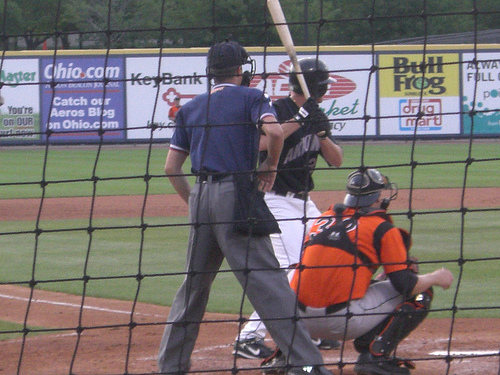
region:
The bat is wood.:
[268, 2, 316, 116]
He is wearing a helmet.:
[290, 51, 340, 93]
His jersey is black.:
[263, 95, 343, 187]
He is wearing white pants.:
[235, 189, 326, 372]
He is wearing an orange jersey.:
[284, 196, 404, 311]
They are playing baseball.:
[10, 25, 497, 373]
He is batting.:
[230, 9, 333, 370]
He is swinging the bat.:
[246, 7, 353, 359]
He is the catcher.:
[300, 168, 453, 362]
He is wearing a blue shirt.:
[153, 49, 282, 191]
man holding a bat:
[290, 30, 336, 172]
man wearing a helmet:
[270, 0, 350, 200]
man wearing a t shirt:
[280, 37, 346, 192]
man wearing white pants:
[266, 0, 326, 238]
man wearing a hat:
[145, 35, 317, 370]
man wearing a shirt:
[110, 25, 312, 367]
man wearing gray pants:
[106, 26, 303, 367]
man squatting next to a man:
[315, 150, 455, 367]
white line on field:
[15, 285, 140, 325]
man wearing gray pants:
[315, 156, 460, 368]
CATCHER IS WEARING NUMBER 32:
[287, 156, 439, 354]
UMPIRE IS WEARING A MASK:
[196, 40, 280, 95]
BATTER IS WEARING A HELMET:
[280, 51, 345, 123]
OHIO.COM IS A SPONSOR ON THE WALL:
[39, 55, 151, 163]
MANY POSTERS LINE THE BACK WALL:
[0, 40, 497, 155]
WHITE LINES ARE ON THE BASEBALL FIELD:
[4, 287, 184, 343]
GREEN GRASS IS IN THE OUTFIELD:
[5, 147, 498, 202]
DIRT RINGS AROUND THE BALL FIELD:
[10, 192, 497, 217]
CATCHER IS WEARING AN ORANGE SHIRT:
[298, 167, 405, 318]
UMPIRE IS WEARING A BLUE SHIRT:
[156, 83, 315, 200]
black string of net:
[7, 4, 498, 366]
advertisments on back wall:
[2, 48, 497, 144]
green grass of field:
[0, 141, 496, 196]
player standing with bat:
[237, 1, 340, 356]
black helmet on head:
[290, 58, 334, 100]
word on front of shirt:
[283, 133, 326, 164]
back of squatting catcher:
[297, 167, 447, 371]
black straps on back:
[304, 203, 378, 265]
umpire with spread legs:
[167, 39, 314, 374]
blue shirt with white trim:
[170, 83, 275, 183]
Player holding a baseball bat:
[259, 0, 343, 133]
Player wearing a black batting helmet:
[282, 53, 343, 107]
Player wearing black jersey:
[264, 90, 336, 205]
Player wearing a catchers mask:
[335, 162, 405, 214]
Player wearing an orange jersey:
[293, 200, 412, 315]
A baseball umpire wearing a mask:
[192, 33, 261, 98]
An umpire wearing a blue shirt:
[159, 78, 284, 196]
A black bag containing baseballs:
[227, 171, 289, 246]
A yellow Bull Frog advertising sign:
[375, 49, 465, 102]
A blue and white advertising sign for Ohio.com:
[36, 56, 131, 140]